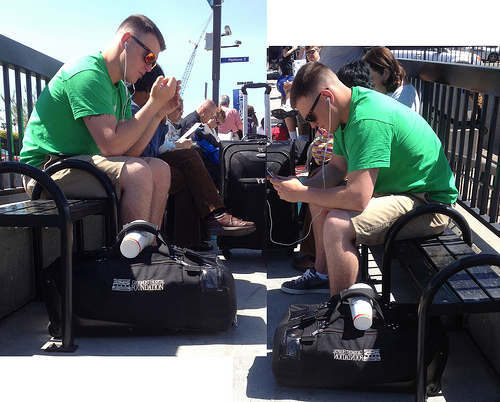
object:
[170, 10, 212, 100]
crane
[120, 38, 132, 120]
earbuds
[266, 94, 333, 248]
headphones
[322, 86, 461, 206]
shirt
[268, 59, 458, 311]
man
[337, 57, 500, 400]
bench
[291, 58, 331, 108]
short hair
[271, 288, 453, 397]
black bag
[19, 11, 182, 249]
man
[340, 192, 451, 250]
shorts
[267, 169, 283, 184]
cell phone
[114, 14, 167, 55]
hair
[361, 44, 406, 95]
hair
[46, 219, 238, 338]
bag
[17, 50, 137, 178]
shirt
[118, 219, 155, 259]
cup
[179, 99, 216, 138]
man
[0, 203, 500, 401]
ground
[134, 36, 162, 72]
sunglasses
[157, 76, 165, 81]
nails